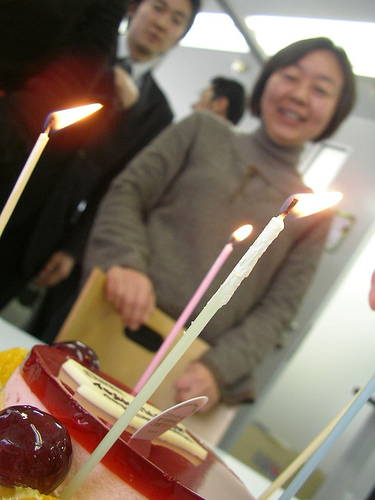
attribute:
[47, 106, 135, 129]
fire — here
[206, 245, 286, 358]
candle — white, pink, blue, yellow, thin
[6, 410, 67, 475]
cherry — red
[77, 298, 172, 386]
chair — brown, wooden, held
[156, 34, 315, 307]
person — standing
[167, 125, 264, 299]
sweater — grey, gray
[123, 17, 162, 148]
man — standing, here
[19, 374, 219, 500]
cake — here, strawberry, birthday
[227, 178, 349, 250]
candles — here, lit, tall, white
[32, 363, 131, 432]
jello — red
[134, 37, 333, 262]
woman — here, smiling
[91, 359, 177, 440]
message — here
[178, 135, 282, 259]
shirt — gray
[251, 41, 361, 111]
hair — black, cut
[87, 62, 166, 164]
suit — black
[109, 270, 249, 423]
hands — resting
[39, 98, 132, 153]
flame — white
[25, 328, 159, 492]
dessert — red, round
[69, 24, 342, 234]
people — looking